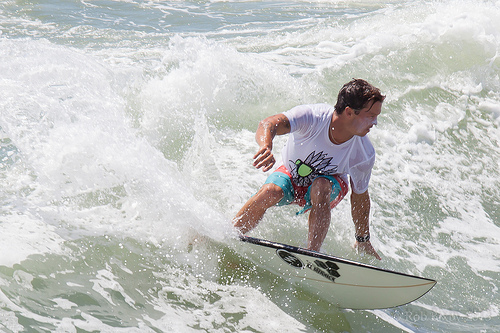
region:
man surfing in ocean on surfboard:
[233, 72, 443, 319]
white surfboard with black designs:
[241, 228, 443, 320]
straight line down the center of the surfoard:
[282, 267, 440, 293]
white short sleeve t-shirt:
[268, 100, 380, 203]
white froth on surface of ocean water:
[84, 261, 142, 313]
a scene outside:
[1, 0, 492, 331]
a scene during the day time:
[4, 4, 496, 330]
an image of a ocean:
[10, 5, 499, 330]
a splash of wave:
[7, 38, 224, 248]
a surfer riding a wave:
[182, 59, 459, 326]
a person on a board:
[199, 60, 456, 330]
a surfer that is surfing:
[169, 55, 447, 332]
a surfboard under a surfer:
[186, 70, 470, 328]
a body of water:
[9, 5, 499, 332]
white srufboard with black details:
[221, 222, 440, 319]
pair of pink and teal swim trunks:
[258, 160, 350, 218]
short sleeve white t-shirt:
[276, 99, 381, 199]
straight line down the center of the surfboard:
[279, 267, 441, 298]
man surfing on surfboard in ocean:
[230, 68, 442, 324]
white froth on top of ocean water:
[87, 257, 139, 312]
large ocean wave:
[18, 37, 329, 161]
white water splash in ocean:
[178, 95, 223, 156]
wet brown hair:
[324, 72, 390, 117]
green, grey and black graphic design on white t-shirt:
[283, 144, 340, 187]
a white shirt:
[335, 148, 365, 165]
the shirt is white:
[331, 145, 362, 166]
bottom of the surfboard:
[362, 272, 389, 300]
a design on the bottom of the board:
[276, 254, 338, 281]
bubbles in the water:
[214, 280, 263, 326]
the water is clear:
[82, 146, 153, 203]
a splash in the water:
[111, 146, 167, 200]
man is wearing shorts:
[271, 169, 293, 186]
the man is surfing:
[236, 73, 399, 253]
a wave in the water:
[172, 43, 267, 109]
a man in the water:
[234, 53, 474, 332]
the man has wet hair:
[312, 57, 419, 149]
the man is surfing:
[186, 56, 446, 318]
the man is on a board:
[208, 55, 454, 322]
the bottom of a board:
[266, 263, 438, 310]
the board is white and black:
[159, 212, 479, 316]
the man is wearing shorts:
[203, 74, 418, 248]